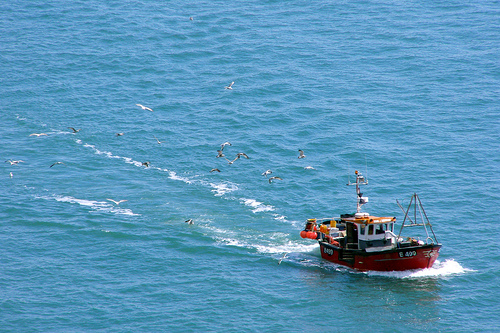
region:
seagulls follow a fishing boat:
[65, 101, 372, 213]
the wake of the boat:
[0, 135, 308, 265]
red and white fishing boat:
[298, 193, 480, 274]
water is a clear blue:
[0, 7, 497, 332]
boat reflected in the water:
[252, 253, 468, 318]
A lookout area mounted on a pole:
[350, 157, 373, 212]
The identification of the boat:
[380, 245, 427, 259]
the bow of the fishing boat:
[403, 220, 443, 272]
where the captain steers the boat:
[350, 218, 395, 249]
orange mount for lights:
[362, 210, 397, 228]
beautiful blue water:
[1, 0, 498, 330]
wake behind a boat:
[6, 115, 321, 260]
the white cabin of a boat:
[360, 217, 398, 243]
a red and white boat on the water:
[290, 199, 444, 281]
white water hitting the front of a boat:
[397, 256, 463, 283]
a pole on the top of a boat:
[345, 164, 372, 215]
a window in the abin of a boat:
[370, 221, 384, 238]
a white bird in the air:
[133, 101, 154, 118]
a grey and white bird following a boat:
[293, 145, 307, 164]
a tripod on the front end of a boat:
[393, 188, 443, 253]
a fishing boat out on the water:
[246, 114, 475, 307]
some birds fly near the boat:
[68, 43, 321, 250]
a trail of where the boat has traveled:
[28, 113, 300, 288]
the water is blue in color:
[36, 18, 471, 172]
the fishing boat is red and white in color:
[292, 162, 449, 280]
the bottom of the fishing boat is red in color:
[313, 238, 448, 281]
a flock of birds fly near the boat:
[56, 55, 323, 269]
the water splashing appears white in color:
[388, 255, 463, 280]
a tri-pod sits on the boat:
[392, 188, 438, 247]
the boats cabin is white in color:
[340, 207, 399, 246]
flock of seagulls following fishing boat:
[9, 72, 329, 252]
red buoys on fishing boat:
[296, 221, 321, 242]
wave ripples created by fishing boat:
[20, 111, 306, 270]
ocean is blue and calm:
[3, 4, 498, 331]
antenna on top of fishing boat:
[346, 163, 373, 217]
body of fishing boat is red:
[316, 235, 445, 275]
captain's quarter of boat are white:
[339, 205, 399, 250]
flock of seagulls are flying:
[4, 52, 321, 253]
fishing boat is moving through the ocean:
[304, 167, 441, 275]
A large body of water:
[0, 0, 498, 332]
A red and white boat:
[300, 155, 447, 271]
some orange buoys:
[298, 217, 320, 241]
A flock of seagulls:
[11, 13, 315, 229]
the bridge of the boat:
[345, 215, 395, 246]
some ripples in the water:
[10, 116, 312, 258]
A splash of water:
[363, 258, 469, 280]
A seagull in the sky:
[221, 78, 239, 93]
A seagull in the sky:
[131, 99, 156, 116]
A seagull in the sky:
[28, 131, 52, 140]